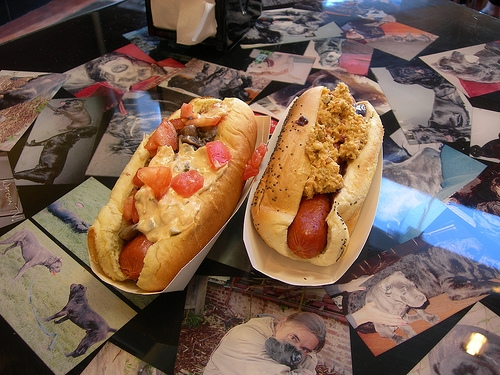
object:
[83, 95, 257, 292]
hotdog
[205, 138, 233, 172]
tomato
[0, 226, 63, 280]
dog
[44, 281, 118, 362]
dog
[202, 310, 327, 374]
man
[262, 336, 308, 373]
dog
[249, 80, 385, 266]
hotdog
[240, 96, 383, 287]
holder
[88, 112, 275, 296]
tray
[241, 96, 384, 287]
trays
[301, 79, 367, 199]
sauce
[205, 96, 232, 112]
mayonnaise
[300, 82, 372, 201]
mustard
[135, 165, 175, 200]
tomatoe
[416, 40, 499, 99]
pictures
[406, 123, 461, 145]
dogs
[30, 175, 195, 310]
photos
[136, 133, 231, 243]
condiments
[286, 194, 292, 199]
black seeds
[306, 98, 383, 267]
bun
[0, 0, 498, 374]
table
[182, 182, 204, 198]
cut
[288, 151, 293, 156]
seeds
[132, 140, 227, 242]
melted cheese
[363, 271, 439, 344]
dog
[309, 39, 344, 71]
dog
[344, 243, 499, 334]
dog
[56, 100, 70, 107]
tounge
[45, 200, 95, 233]
dog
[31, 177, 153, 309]
grass